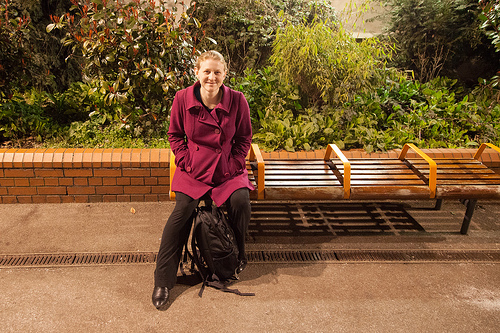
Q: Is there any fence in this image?
A: No, there are no fences.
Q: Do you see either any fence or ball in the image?
A: No, there are no fences or balls.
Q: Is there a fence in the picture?
A: No, there are no fences.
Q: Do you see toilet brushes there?
A: No, there are no toilet brushes.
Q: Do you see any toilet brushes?
A: No, there are no toilet brushes.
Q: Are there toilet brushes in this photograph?
A: No, there are no toilet brushes.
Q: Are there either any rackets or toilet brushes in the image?
A: No, there are no toilet brushes or rackets.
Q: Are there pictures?
A: No, there are no pictures.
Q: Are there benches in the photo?
A: Yes, there is a bench.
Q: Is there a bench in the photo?
A: Yes, there is a bench.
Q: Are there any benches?
A: Yes, there is a bench.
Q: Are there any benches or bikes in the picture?
A: Yes, there is a bench.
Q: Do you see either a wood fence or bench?
A: Yes, there is a wood bench.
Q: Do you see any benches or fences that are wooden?
A: Yes, the bench is wooden.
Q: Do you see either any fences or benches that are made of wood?
A: Yes, the bench is made of wood.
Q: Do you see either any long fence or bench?
A: Yes, there is a long bench.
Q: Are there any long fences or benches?
A: Yes, there is a long bench.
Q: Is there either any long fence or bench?
A: Yes, there is a long bench.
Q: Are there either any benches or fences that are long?
A: Yes, the bench is long.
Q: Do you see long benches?
A: Yes, there is a long bench.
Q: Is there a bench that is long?
A: Yes, there is a bench that is long.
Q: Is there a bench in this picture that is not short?
A: Yes, there is a long bench.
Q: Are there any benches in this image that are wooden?
A: Yes, there is a wood bench.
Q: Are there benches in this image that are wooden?
A: Yes, there is a bench that is wooden.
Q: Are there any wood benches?
A: Yes, there is a bench that is made of wood.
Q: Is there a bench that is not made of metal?
A: Yes, there is a bench that is made of wood.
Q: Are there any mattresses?
A: No, there are no mattresses.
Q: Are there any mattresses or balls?
A: No, there are no mattresses or balls.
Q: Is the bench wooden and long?
A: Yes, the bench is wooden and long.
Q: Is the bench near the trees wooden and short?
A: No, the bench is wooden but long.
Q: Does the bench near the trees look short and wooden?
A: No, the bench is wooden but long.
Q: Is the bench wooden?
A: Yes, the bench is wooden.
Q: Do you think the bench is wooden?
A: Yes, the bench is wooden.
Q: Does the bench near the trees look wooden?
A: Yes, the bench is wooden.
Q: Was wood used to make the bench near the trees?
A: Yes, the bench is made of wood.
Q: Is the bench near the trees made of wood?
A: Yes, the bench is made of wood.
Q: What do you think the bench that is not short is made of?
A: The bench is made of wood.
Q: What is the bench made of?
A: The bench is made of wood.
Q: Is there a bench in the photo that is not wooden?
A: No, there is a bench but it is wooden.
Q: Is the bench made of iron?
A: No, the bench is made of wood.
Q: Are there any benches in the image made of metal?
A: No, there is a bench but it is made of wood.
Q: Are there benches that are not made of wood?
A: No, there is a bench but it is made of wood.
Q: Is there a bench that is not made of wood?
A: No, there is a bench but it is made of wood.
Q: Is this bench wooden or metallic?
A: The bench is wooden.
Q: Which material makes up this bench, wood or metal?
A: The bench is made of wood.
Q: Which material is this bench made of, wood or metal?
A: The bench is made of wood.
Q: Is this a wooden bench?
A: Yes, this is a wooden bench.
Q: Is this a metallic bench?
A: No, this is a wooden bench.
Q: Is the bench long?
A: Yes, the bench is long.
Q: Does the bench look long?
A: Yes, the bench is long.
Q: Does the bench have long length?
A: Yes, the bench is long.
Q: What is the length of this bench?
A: The bench is long.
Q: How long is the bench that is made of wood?
A: The bench is long.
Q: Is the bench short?
A: No, the bench is long.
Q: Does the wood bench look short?
A: No, the bench is long.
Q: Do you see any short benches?
A: No, there is a bench but it is long.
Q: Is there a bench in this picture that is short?
A: No, there is a bench but it is long.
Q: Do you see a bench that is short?
A: No, there is a bench but it is long.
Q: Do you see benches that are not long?
A: No, there is a bench but it is long.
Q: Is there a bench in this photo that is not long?
A: No, there is a bench but it is long.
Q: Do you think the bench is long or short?
A: The bench is long.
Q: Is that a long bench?
A: Yes, that is a long bench.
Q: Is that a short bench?
A: No, that is a long bench.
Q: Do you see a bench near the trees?
A: Yes, there is a bench near the trees.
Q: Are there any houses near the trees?
A: No, there is a bench near the trees.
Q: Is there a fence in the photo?
A: No, there are no fences.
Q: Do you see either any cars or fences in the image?
A: No, there are no fences or cars.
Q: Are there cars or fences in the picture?
A: No, there are no fences or cars.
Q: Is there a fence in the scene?
A: No, there are no fences.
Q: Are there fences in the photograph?
A: No, there are no fences.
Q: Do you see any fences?
A: No, there are no fences.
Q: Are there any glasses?
A: No, there are no glasses.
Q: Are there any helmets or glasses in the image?
A: No, there are no glasses or helmets.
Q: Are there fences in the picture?
A: No, there are no fences.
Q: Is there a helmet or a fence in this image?
A: No, there are no fences or helmets.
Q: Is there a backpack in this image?
A: Yes, there is a backpack.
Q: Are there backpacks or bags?
A: Yes, there is a backpack.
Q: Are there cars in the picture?
A: No, there are no cars.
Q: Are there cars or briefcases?
A: No, there are no cars or briefcases.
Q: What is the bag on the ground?
A: The bag is a backpack.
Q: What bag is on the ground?
A: The bag is a backpack.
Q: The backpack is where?
A: The backpack is on the ground.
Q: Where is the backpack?
A: The backpack is on the ground.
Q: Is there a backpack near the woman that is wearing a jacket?
A: Yes, there is a backpack near the woman.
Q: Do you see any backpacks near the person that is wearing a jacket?
A: Yes, there is a backpack near the woman.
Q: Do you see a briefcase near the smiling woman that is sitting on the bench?
A: No, there is a backpack near the woman.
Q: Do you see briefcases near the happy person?
A: No, there is a backpack near the woman.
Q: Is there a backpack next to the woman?
A: Yes, there is a backpack next to the woman.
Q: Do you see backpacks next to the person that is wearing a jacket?
A: Yes, there is a backpack next to the woman.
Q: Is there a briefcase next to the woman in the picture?
A: No, there is a backpack next to the woman.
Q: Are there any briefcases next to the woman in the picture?
A: No, there is a backpack next to the woman.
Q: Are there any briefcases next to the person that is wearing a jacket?
A: No, there is a backpack next to the woman.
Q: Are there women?
A: Yes, there is a woman.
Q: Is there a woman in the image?
A: Yes, there is a woman.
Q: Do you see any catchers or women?
A: Yes, there is a woman.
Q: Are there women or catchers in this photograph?
A: Yes, there is a woman.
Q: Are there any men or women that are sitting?
A: Yes, the woman is sitting.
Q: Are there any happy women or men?
A: Yes, there is a happy woman.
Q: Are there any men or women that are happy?
A: Yes, the woman is happy.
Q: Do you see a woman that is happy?
A: Yes, there is a happy woman.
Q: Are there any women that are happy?
A: Yes, there is a woman that is happy.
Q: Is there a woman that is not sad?
A: Yes, there is a happy woman.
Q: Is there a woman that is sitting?
A: Yes, there is a woman that is sitting.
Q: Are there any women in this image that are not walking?
A: Yes, there is a woman that is sitting.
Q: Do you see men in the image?
A: No, there are no men.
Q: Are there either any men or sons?
A: No, there are no men or sons.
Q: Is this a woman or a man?
A: This is a woman.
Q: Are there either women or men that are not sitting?
A: No, there is a woman but she is sitting.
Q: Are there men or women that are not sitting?
A: No, there is a woman but she is sitting.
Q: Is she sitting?
A: Yes, the woman is sitting.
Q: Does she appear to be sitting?
A: Yes, the woman is sitting.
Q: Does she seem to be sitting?
A: Yes, the woman is sitting.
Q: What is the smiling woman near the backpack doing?
A: The woman is sitting.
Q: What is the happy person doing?
A: The woman is sitting.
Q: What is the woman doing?
A: The woman is sitting.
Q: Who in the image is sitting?
A: The woman is sitting.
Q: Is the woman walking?
A: No, the woman is sitting.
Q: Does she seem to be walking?
A: No, the woman is sitting.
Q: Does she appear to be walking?
A: No, the woman is sitting.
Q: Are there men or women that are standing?
A: No, there is a woman but she is sitting.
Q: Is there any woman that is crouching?
A: No, there is a woman but she is sitting.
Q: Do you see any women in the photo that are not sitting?
A: No, there is a woman but she is sitting.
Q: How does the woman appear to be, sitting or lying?
A: The woman is sitting.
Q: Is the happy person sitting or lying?
A: The woman is sitting.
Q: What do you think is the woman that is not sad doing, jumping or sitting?
A: The woman is sitting.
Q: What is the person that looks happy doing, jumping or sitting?
A: The woman is sitting.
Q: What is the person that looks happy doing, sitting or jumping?
A: The woman is sitting.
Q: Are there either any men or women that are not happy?
A: No, there is a woman but she is happy.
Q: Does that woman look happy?
A: Yes, the woman is happy.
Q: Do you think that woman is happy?
A: Yes, the woman is happy.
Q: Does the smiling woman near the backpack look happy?
A: Yes, the woman is happy.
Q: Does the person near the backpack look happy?
A: Yes, the woman is happy.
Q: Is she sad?
A: No, the woman is happy.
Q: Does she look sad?
A: No, the woman is happy.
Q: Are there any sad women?
A: No, there is a woman but she is happy.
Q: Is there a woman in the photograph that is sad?
A: No, there is a woman but she is happy.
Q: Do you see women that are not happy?
A: No, there is a woman but she is happy.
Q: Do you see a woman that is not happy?
A: No, there is a woman but she is happy.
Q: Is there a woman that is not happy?
A: No, there is a woman but she is happy.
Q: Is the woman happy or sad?
A: The woman is happy.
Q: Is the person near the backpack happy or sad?
A: The woman is happy.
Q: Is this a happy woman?
A: Yes, this is a happy woman.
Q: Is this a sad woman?
A: No, this is a happy woman.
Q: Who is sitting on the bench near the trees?
A: The woman is sitting on the bench.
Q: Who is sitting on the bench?
A: The woman is sitting on the bench.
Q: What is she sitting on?
A: The woman is sitting on the bench.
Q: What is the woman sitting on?
A: The woman is sitting on the bench.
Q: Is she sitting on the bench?
A: Yes, the woman is sitting on the bench.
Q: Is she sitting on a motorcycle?
A: No, the woman is sitting on the bench.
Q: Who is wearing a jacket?
A: The woman is wearing a jacket.